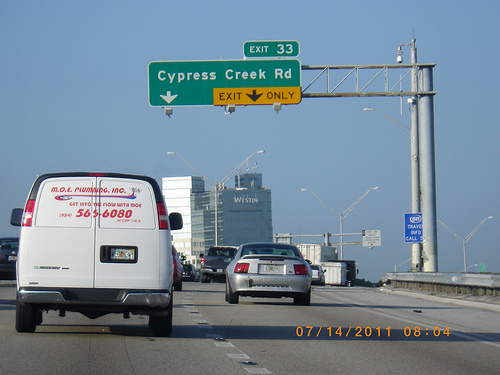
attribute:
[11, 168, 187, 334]
van — white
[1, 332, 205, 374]
street — grey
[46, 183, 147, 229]
sign — red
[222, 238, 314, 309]
car — silver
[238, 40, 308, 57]
sign — green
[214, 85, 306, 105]
sign — yellow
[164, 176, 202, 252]
building — white, tall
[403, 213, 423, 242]
sign — blue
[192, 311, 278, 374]
line — white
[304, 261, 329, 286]
truck — white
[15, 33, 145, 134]
sky — blue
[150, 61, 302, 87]
sign — green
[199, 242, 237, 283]
truck — black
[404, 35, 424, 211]
pole — grey